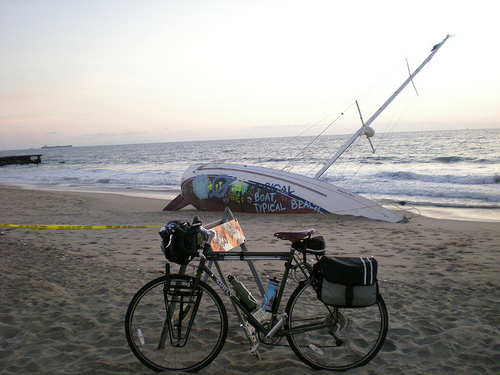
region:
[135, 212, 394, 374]
bike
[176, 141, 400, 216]
boat on sand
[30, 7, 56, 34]
white clouds in blue sky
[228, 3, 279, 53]
white clouds in blue sky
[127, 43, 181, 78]
white clouds in blue sky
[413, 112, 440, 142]
white clouds in blue sky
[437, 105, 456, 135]
white clouds in blue sky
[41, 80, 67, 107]
white clouds in blue sky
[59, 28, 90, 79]
white clouds in blue sky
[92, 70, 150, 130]
white clouds in blue sky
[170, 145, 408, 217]
boat on beach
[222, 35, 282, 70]
white clouds in blue sky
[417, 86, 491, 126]
white clouds in blue sky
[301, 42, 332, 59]
white clouds in blue sky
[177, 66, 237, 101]
white clouds in blue sky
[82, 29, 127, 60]
white clouds in blue sky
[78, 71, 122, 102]
white clouds in blue sky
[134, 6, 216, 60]
white clouds in blue sky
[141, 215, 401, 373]
black bike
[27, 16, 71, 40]
white clouds in blue sky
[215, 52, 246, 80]
white clouds in blue sky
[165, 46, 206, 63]
white clouds in blue sky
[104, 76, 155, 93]
white clouds in blue sky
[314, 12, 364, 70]
white clouds in blue sky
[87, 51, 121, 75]
white clouds in blue sky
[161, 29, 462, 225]
a sailboat on its side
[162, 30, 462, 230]
a sailboat stranded on a beach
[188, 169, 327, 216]
graffiti on a sailboat's hull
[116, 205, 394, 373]
a bicycle on the beach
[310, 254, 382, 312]
a black and gray bag on the back of the bicycle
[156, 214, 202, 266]
a black helmet hanging from the handlebars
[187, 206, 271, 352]
an orange and white post holding up the yellow tape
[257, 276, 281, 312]
a blue water bottle on the bike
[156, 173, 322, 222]
bottom of the sailboat is red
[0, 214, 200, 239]
yellow caution tape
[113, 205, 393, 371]
A bicycle on the beach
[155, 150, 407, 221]
A boat is on the beach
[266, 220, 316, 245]
A bicycle seat on bike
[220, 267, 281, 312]
Two thermoses on the bicycle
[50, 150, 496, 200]
Waves in the ocean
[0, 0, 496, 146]
The sky appears overcast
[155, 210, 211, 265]
A basket on the bicycle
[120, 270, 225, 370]
A round black wheel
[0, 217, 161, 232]
A piece of yellow tape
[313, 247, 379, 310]
White stripes on a black and beige bag